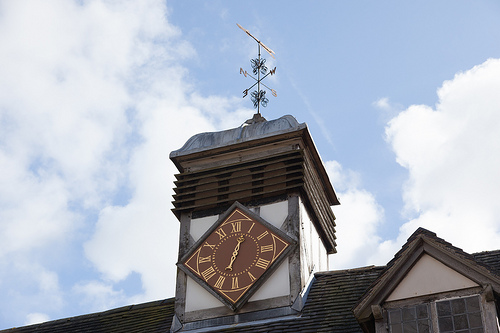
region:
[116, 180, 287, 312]
this is a clock tower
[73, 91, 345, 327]
the tower is wooden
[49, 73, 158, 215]
this is a cloud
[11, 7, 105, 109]
the cloud is white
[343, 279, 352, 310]
this is a roof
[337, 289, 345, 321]
the roof is wooden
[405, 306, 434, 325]
this is a window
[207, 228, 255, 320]
the clock is a square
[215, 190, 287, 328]
the clock is maroon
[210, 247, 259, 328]
the hands are gold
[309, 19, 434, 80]
this is the sky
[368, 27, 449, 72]
the sky is blue in color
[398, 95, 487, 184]
this is the cloud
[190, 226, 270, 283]
this is a clock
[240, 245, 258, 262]
the wall is brown in color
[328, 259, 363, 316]
this is the roof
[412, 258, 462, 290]
this is the wall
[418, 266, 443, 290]
the wall is white in color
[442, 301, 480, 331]
this is a window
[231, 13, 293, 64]
this is a compass direction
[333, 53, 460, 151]
the sky is blue in colour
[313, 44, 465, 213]
the sky is cloudy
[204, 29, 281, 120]
the chimney has a compass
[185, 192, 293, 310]
a clock is on the tower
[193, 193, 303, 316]
the clock is diamond shaped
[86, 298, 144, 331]
the roof is grey in colour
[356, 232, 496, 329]
the roof is triangular shaped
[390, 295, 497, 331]
the house has a window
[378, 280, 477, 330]
the window has glass panes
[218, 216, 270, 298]
the clock is brown in colour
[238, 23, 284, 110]
weather vane on top of a building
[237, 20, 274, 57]
arrow pointing north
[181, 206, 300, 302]
diamond shaped clock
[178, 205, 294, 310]
brown clock with gold numbers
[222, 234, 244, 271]
hands of the clock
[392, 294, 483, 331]
window on the building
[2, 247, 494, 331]
black shingles on the roof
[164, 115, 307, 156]
metal roof below weather vane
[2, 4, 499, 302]
partly cloudy sky above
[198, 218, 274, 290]
gold roman numerals on a clock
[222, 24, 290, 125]
top tower of the pillar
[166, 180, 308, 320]
a watch in tower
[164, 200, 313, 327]
a clock in tower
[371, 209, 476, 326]
top part of home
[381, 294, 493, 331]
a glass windows in top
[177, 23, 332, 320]
a top tower of home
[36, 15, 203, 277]
clouds in the sky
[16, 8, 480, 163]
beautiful view of sky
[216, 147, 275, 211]
small gaps in tower